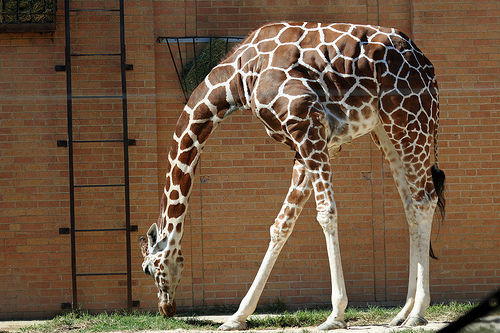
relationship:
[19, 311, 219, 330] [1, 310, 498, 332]
grass on ground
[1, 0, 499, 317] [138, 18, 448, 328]
wall behind giraffe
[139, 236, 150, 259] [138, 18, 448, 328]
horns on giraffe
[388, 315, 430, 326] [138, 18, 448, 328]
hoofs on giraffe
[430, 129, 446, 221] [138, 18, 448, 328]
tail on giraffe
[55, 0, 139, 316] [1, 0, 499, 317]
ladder on wall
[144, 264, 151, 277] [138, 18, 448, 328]
eye of giraffe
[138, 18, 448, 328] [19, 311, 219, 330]
giraffe eats grass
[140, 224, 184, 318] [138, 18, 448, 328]
head of giraffe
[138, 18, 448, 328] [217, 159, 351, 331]
giraffe has legs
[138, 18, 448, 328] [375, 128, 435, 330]
giraffe has hind legs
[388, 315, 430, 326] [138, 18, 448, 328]
hoofs of giraffe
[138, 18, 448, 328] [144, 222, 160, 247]
giraffe has ear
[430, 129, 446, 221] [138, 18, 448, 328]
tail of giraffe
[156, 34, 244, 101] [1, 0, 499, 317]
feeder on wall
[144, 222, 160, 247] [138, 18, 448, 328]
ear of giraffe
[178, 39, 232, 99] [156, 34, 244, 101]
hay in feeder